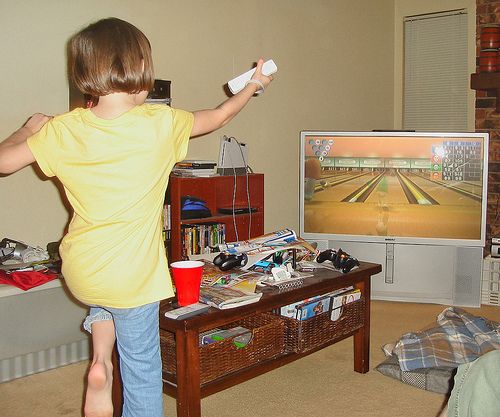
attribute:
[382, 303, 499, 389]
blanket — plaid, blue, white, beige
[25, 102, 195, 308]
shirt — yellow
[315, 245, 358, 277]
controller — black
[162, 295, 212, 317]
remote control — white and gray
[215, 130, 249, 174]
gaming system — white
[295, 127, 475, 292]
tv — on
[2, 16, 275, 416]
girl — little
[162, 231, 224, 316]
cup — red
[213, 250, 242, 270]
remote control —  remote,  Playstation's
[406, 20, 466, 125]
blinds — white, horizontal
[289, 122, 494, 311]
tv — large, silver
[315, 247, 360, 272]
controller — black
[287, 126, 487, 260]
tv — big, silver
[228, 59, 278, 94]
control —  White,  Wii's,  remote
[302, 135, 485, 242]
video game — interactive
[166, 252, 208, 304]
cup — red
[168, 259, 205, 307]
red cup — plastic 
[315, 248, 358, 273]
playstation —  Black